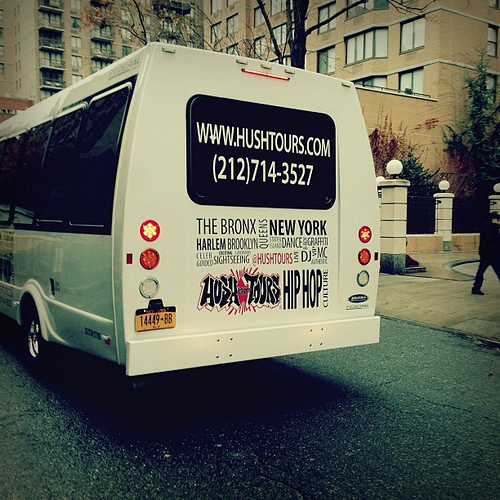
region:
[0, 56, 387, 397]
a white bus with large windows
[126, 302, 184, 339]
a yellow and black tag on a bus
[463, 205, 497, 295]
a person walking on a side walk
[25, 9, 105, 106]
a building with balconies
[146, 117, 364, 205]
white letters and numbers painted on a bus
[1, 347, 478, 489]
a black paved road way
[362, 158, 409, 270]
a column with a light on top of it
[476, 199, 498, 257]
a man wearing a hat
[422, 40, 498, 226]
a tall green tree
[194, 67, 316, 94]
rear break light on a bus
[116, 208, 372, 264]
the brake lights are red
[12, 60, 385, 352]
the mini bus is white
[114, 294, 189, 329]
the license plate is yellow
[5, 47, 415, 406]
the vehicle is on the street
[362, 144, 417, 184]
light globes on the building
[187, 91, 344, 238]
a black window on the back of the bus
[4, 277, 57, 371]
1 wheel of the bus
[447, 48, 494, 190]
tall green tree in front of building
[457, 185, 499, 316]
a person is walking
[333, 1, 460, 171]
the building is tan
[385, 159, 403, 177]
white glob light on to of cement post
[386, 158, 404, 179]
globe light next to globe light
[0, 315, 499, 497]
black asphalt street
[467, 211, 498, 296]
person walking on sidewalk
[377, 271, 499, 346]
sidewalk is gray cement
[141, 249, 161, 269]
round red taillight on bus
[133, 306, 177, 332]
yellow license plate on bus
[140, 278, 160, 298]
round white light under red taillight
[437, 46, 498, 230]
tall pine tree next to large tan building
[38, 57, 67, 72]
balcony on building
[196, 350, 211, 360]
back of a bus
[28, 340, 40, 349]
wheel of a bus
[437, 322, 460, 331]
edge of a road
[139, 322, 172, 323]
number plate of a bus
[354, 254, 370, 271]
back light of a bus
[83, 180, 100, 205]
part of a window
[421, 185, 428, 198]
part of a fence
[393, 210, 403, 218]
edge of a wall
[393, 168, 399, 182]
bulb on a fence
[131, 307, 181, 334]
yellow and black license plate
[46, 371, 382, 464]
shadow of a truck on the ground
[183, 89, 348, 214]
back windshield on a tour bus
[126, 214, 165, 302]
trio of lights on the back of a bus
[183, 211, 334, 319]
advertisement in black on the back of a bus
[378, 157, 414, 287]
stone pedestal with light orb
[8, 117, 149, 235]
tinted windows on a tour bus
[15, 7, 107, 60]
large apartment building with balconies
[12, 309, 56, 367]
wheel on a tour bus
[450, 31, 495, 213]
tall green pine tree